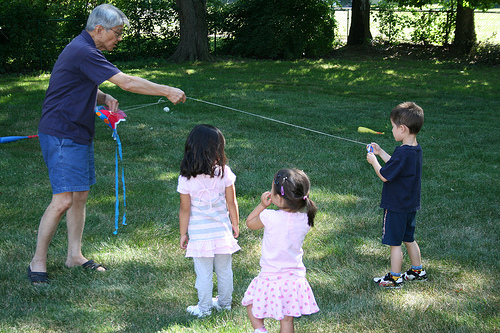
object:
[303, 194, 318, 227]
ponytail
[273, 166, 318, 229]
hair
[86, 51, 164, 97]
arm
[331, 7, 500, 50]
fence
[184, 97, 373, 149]
string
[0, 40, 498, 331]
grass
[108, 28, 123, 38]
glasses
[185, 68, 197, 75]
light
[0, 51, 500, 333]
ground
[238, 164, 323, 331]
girl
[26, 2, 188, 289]
adult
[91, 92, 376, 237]
kite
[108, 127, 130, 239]
tail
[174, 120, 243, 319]
girl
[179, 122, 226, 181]
hair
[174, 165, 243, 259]
shirt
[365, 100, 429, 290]
boy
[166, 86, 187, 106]
hand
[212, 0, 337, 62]
thick bush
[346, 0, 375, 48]
tree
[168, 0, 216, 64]
tree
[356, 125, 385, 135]
toy bat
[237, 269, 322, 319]
shirt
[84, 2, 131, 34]
hair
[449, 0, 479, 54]
trees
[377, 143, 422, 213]
blue shirt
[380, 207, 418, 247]
blue shorts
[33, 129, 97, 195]
blue shorts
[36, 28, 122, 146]
blue shirt